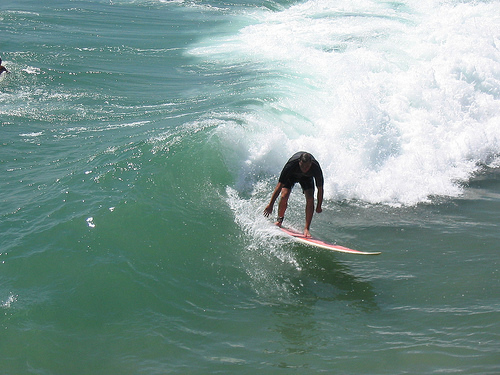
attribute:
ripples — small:
[342, 306, 410, 356]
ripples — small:
[192, 295, 235, 318]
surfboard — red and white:
[267, 220, 382, 260]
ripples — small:
[79, 92, 143, 140]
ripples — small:
[37, 141, 152, 229]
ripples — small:
[336, 262, 424, 292]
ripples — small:
[367, 296, 497, 368]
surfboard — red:
[266, 218, 383, 256]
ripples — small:
[4, 120, 195, 311]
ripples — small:
[342, 256, 419, 294]